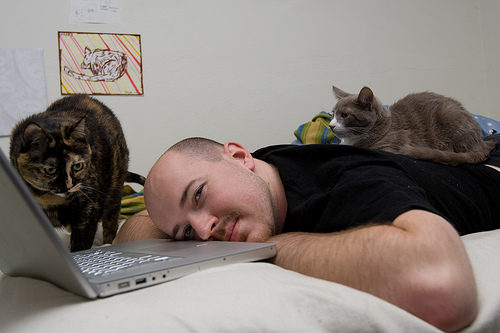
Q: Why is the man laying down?
A: Resting.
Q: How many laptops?
A: One.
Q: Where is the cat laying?
A: On the man's back.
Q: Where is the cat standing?
A: On the bed.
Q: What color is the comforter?
A: White.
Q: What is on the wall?
A: A picture.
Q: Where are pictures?
A: On the wall.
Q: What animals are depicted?
A: Cats.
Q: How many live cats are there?
A: 2.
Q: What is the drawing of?
A: Cat.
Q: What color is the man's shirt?
A: Black.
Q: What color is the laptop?
A: Gray.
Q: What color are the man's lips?
A: Pink.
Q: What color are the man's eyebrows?
A: Brown.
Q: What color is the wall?
A: White.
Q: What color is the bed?
A: White.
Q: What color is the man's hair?
A: Brown.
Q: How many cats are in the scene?
A: Two.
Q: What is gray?
A: Cat on man's back.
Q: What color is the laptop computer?
A: Silver.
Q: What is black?
A: Man's shirt.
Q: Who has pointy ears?
A: The cats.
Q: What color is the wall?
A: White.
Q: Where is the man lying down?
A: On a bed.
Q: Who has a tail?
A: Cats.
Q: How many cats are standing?
A: One.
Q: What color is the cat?
A: Brown.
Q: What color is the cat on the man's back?
A: Gray.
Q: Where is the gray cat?
A: On man's back.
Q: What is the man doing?
A: Laying with cats.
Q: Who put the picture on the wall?
A: Owner.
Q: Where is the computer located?
A: On bed.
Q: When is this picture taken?
A: Day time.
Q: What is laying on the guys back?
A: Cat.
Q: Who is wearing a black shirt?
A: Man.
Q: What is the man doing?
A: Laying down.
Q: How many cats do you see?
A: Two.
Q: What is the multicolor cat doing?
A: Standing near the laptop.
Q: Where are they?
A: In a bedroom.